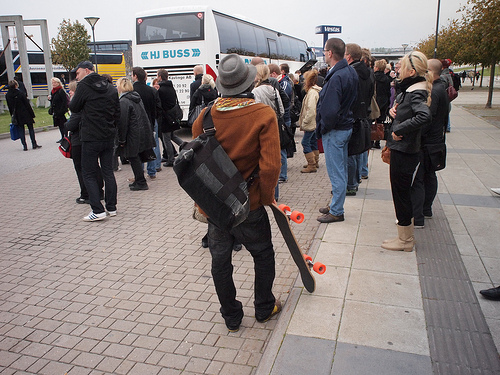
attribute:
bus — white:
[119, 6, 332, 128]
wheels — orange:
[273, 171, 390, 321]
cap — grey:
[214, 52, 258, 96]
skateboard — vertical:
[261, 199, 330, 295]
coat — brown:
[189, 95, 278, 224]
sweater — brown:
[185, 98, 280, 201]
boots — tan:
[374, 221, 419, 253]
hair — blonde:
[402, 50, 429, 77]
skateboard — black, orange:
[267, 202, 327, 295]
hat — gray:
[214, 52, 257, 94]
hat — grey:
[212, 49, 258, 98]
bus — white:
[131, 2, 316, 124]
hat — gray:
[194, 49, 263, 96]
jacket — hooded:
[113, 92, 153, 158]